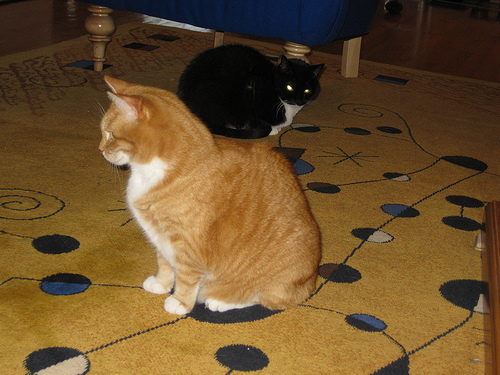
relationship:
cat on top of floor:
[178, 44, 313, 140] [424, 98, 475, 128]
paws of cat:
[127, 276, 189, 315] [178, 44, 313, 140]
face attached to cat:
[92, 102, 179, 166] [178, 44, 313, 140]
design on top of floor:
[343, 184, 412, 249] [424, 98, 475, 128]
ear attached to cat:
[109, 91, 155, 130] [178, 44, 313, 140]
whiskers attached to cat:
[272, 105, 293, 121] [178, 44, 313, 140]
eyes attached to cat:
[275, 80, 314, 95] [178, 44, 313, 140]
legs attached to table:
[71, 10, 117, 70] [271, 1, 338, 33]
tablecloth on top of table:
[209, 16, 229, 22] [271, 1, 338, 33]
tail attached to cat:
[210, 122, 280, 146] [178, 44, 313, 140]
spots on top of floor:
[126, 37, 170, 54] [424, 98, 475, 128]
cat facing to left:
[178, 44, 313, 140] [9, 34, 83, 331]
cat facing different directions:
[178, 44, 313, 140] [57, 308, 447, 345]